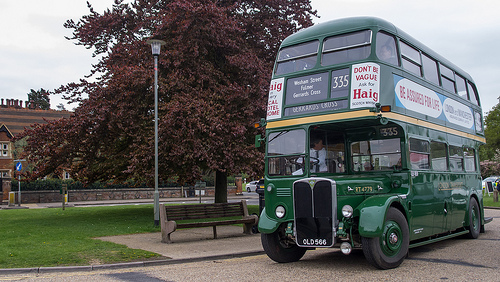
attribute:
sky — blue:
[0, 2, 496, 83]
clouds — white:
[5, 7, 46, 49]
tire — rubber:
[346, 204, 434, 271]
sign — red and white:
[348, 62, 380, 111]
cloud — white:
[8, 9, 72, 83]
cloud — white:
[432, 22, 497, 73]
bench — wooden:
[140, 166, 265, 245]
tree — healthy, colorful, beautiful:
[92, 8, 256, 210]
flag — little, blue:
[12, 160, 30, 175]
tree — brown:
[13, 0, 315, 197]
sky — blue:
[411, 4, 495, 51]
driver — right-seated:
[306, 135, 330, 171]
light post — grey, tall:
[153, 38, 176, 219]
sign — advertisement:
[347, 54, 380, 114]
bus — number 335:
[231, 6, 498, 276]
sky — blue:
[3, 0, 499, 116]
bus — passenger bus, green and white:
[248, 11, 484, 276]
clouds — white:
[4, 4, 484, 112]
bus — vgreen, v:
[281, 15, 492, 263]